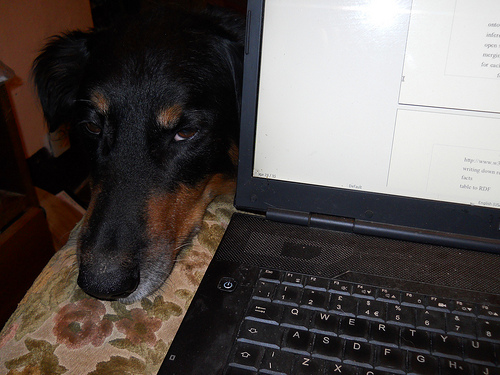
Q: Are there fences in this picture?
A: No, there are no fences.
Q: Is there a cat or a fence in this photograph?
A: No, there are no fences or cats.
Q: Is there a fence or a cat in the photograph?
A: No, there are no fences or cats.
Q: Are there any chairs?
A: Yes, there is a chair.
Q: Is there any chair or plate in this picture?
A: Yes, there is a chair.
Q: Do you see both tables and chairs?
A: No, there is a chair but no tables.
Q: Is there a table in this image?
A: No, there are no tables.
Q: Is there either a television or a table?
A: No, there are no tables or televisions.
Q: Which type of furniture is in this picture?
A: The furniture is a chair.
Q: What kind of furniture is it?
A: The piece of furniture is a chair.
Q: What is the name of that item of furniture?
A: That is a chair.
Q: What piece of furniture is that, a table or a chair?
A: That is a chair.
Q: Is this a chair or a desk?
A: This is a chair.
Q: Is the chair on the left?
A: Yes, the chair is on the left of the image.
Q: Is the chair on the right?
A: No, the chair is on the left of the image.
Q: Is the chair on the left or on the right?
A: The chair is on the left of the image.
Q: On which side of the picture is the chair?
A: The chair is on the left of the image.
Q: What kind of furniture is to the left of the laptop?
A: The piece of furniture is a chair.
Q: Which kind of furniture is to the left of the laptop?
A: The piece of furniture is a chair.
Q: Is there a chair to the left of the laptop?
A: Yes, there is a chair to the left of the laptop.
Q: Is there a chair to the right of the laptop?
A: No, the chair is to the left of the laptop.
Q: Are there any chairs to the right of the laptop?
A: No, the chair is to the left of the laptop.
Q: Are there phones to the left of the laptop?
A: No, there is a chair to the left of the laptop.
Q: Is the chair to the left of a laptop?
A: Yes, the chair is to the left of a laptop.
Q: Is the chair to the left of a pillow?
A: No, the chair is to the left of a laptop.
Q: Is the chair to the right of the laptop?
A: No, the chair is to the left of the laptop.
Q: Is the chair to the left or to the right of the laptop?
A: The chair is to the left of the laptop.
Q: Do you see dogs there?
A: Yes, there is a dog.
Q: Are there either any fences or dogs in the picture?
A: Yes, there is a dog.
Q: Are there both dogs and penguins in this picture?
A: No, there is a dog but no penguins.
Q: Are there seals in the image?
A: No, there are no seals.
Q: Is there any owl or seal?
A: No, there are no seals or owls.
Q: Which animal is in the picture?
A: The animal is a dog.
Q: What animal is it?
A: The animal is a dog.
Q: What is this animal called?
A: This is a dog.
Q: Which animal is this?
A: This is a dog.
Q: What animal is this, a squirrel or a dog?
A: This is a dog.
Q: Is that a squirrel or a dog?
A: That is a dog.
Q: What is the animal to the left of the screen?
A: The animal is a dog.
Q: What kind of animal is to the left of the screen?
A: The animal is a dog.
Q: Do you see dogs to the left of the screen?
A: Yes, there is a dog to the left of the screen.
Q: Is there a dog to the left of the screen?
A: Yes, there is a dog to the left of the screen.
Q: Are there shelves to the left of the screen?
A: No, there is a dog to the left of the screen.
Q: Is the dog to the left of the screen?
A: Yes, the dog is to the left of the screen.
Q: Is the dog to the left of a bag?
A: No, the dog is to the left of the screen.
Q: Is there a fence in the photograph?
A: No, there are no fences.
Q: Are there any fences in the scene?
A: No, there are no fences.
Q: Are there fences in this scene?
A: No, there are no fences.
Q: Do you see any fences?
A: No, there are no fences.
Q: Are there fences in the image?
A: No, there are no fences.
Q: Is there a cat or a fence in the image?
A: No, there are no fences or cats.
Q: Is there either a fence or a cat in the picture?
A: No, there are no fences or cats.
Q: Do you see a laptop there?
A: Yes, there is a laptop.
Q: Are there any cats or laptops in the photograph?
A: Yes, there is a laptop.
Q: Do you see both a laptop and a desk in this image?
A: No, there is a laptop but no desks.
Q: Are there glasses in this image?
A: No, there are no glasses.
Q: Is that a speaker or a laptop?
A: That is a laptop.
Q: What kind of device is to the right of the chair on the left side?
A: The device is a laptop.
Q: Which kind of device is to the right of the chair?
A: The device is a laptop.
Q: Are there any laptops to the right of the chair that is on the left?
A: Yes, there is a laptop to the right of the chair.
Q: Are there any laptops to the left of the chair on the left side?
A: No, the laptop is to the right of the chair.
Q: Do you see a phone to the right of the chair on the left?
A: No, there is a laptop to the right of the chair.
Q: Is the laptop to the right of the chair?
A: Yes, the laptop is to the right of the chair.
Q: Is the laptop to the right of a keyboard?
A: No, the laptop is to the right of the chair.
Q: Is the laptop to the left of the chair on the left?
A: No, the laptop is to the right of the chair.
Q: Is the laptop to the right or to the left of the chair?
A: The laptop is to the right of the chair.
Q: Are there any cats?
A: No, there are no cats.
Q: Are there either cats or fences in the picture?
A: No, there are no cats or fences.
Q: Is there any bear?
A: No, there are no bears.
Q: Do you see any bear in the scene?
A: No, there are no bears.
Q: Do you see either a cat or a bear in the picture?
A: No, there are no bears or cats.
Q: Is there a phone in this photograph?
A: No, there are no phones.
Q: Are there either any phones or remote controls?
A: No, there are no phones or remote controls.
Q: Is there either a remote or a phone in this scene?
A: No, there are no phones or remote controls.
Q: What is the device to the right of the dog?
A: The device is a screen.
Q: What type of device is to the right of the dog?
A: The device is a screen.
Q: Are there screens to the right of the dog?
A: Yes, there is a screen to the right of the dog.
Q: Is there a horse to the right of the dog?
A: No, there is a screen to the right of the dog.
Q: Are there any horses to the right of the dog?
A: No, there is a screen to the right of the dog.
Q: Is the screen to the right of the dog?
A: Yes, the screen is to the right of the dog.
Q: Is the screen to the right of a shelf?
A: No, the screen is to the right of the dog.